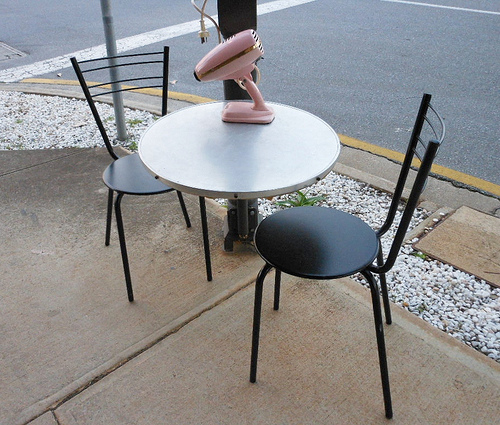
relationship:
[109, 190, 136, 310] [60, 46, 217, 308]
leg of chair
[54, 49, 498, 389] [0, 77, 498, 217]
gravel along edge of sidewalk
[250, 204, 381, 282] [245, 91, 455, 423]
seat of chair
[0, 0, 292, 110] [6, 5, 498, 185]
line on road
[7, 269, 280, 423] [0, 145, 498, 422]
crack in sidewalk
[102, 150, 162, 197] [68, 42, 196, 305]
seat of chair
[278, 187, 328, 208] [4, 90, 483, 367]
weeds in gravel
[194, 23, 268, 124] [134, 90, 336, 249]
object on table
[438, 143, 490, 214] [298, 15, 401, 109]
line along side of road